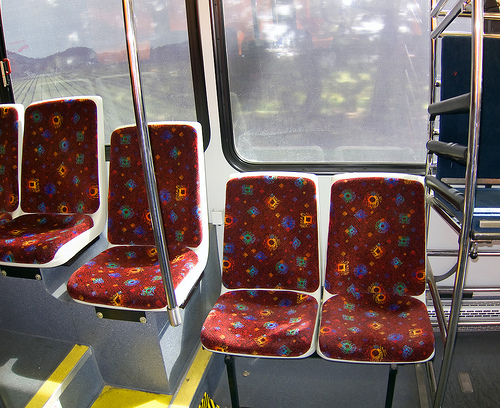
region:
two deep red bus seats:
[199, 158, 435, 377]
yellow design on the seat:
[366, 192, 381, 211]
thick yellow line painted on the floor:
[6, 344, 84, 406]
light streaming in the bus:
[161, 330, 184, 362]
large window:
[222, 4, 434, 159]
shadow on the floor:
[18, 336, 81, 381]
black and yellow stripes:
[197, 391, 216, 407]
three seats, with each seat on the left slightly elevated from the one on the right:
[22, 98, 324, 368]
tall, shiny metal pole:
[426, 7, 498, 407]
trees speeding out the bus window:
[232, 3, 432, 155]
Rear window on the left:
[3, 0, 206, 135]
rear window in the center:
[217, 1, 442, 183]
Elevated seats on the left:
[1, 67, 215, 343]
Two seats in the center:
[205, 160, 457, 402]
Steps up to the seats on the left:
[0, 315, 188, 406]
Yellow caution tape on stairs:
[25, 330, 94, 406]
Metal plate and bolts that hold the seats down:
[1, 262, 153, 332]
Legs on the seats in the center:
[210, 355, 422, 407]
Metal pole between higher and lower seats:
[108, 3, 189, 323]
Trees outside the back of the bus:
[258, 2, 420, 159]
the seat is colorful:
[208, 191, 375, 393]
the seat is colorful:
[176, 131, 413, 366]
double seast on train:
[208, 159, 433, 368]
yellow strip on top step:
[37, 340, 89, 403]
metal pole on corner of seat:
[119, 75, 194, 326]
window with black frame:
[206, 53, 320, 175]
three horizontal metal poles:
[424, 83, 481, 212]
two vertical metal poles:
[419, 11, 484, 103]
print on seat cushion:
[336, 300, 408, 349]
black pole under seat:
[218, 351, 253, 400]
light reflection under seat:
[155, 308, 192, 378]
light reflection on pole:
[122, 22, 156, 93]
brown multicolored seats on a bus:
[318, 177, 427, 362]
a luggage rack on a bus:
[423, 2, 499, 407]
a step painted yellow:
[78, 378, 185, 405]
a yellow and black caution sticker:
[193, 393, 221, 406]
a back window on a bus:
[208, 0, 455, 188]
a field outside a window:
[20, 73, 174, 126]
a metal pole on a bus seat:
[110, 9, 184, 331]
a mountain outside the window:
[4, 35, 97, 77]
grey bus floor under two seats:
[224, 339, 422, 407]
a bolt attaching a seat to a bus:
[29, 272, 44, 282]